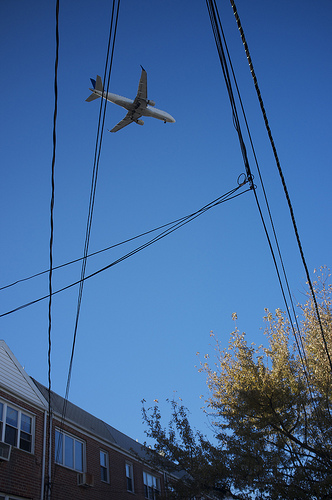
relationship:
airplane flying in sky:
[85, 67, 174, 136] [2, 0, 331, 464]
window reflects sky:
[57, 425, 85, 469] [2, 0, 331, 464]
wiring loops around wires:
[232, 169, 264, 198] [200, 2, 330, 464]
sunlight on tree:
[203, 258, 331, 408] [120, 284, 323, 499]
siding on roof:
[4, 346, 52, 406] [35, 368, 201, 495]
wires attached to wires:
[200, 2, 330, 464] [6, 154, 254, 338]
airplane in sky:
[85, 67, 174, 136] [2, 0, 331, 464]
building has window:
[3, 343, 222, 499] [57, 425, 85, 469]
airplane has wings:
[85, 67, 174, 136] [108, 65, 151, 140]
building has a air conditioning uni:
[3, 343, 222, 499] [76, 464, 96, 493]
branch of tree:
[210, 313, 331, 452] [120, 284, 323, 499]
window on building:
[57, 425, 85, 469] [3, 343, 222, 499]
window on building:
[143, 465, 168, 499] [3, 343, 222, 499]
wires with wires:
[200, 2, 330, 464] [6, 154, 254, 338]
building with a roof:
[3, 343, 222, 499] [35, 368, 201, 495]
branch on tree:
[210, 313, 331, 452] [120, 284, 323, 499]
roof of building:
[35, 368, 201, 495] [3, 343, 222, 499]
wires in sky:
[200, 2, 330, 464] [2, 0, 331, 464]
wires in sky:
[6, 154, 254, 338] [2, 0, 331, 464]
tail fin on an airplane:
[91, 76, 101, 94] [85, 67, 174, 136]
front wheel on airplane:
[163, 119, 171, 127] [85, 67, 174, 136]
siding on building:
[4, 346, 52, 406] [3, 343, 222, 499]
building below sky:
[3, 343, 222, 499] [2, 0, 331, 464]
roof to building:
[35, 368, 201, 495] [3, 343, 222, 499]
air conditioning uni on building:
[76, 464, 96, 493] [3, 343, 222, 499]